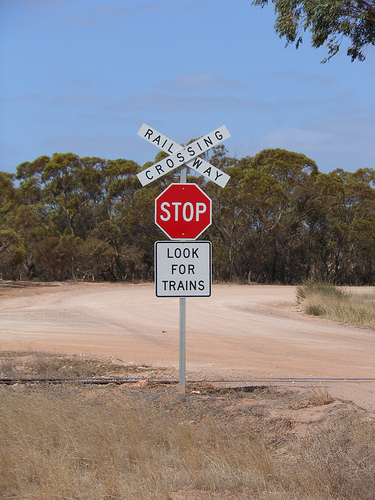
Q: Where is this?
A: This is at the road.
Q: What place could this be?
A: It is a road.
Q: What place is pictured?
A: It is a road.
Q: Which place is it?
A: It is a road.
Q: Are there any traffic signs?
A: Yes, there is a traffic sign.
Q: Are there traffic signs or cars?
A: Yes, there is a traffic sign.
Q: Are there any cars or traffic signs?
A: Yes, there is a traffic sign.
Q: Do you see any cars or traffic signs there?
A: Yes, there is a traffic sign.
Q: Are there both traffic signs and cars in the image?
A: No, there is a traffic sign but no cars.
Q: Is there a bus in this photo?
A: No, there are no buses.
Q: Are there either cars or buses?
A: No, there are no buses or cars.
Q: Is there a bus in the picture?
A: No, there are no buses.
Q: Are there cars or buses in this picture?
A: No, there are no buses or cars.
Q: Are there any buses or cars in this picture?
A: No, there are no buses or cars.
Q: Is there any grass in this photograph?
A: Yes, there is grass.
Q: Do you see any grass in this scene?
A: Yes, there is grass.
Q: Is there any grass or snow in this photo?
A: Yes, there is grass.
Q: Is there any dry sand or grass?
A: Yes, there is dry grass.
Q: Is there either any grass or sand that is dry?
A: Yes, the grass is dry.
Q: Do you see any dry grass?
A: Yes, there is dry grass.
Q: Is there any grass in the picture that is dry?
A: Yes, there is grass that is dry.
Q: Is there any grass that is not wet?
A: Yes, there is dry grass.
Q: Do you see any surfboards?
A: No, there are no surfboards.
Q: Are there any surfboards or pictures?
A: No, there are no surfboards or pictures.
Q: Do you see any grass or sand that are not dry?
A: No, there is grass but it is dry.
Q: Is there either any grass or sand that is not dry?
A: No, there is grass but it is dry.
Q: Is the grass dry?
A: Yes, the grass is dry.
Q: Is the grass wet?
A: No, the grass is dry.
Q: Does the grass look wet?
A: No, the grass is dry.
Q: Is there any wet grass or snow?
A: No, there is grass but it is dry.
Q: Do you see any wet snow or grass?
A: No, there is grass but it is dry.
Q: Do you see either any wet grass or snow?
A: No, there is grass but it is dry.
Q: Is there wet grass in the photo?
A: No, there is grass but it is dry.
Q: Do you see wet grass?
A: No, there is grass but it is dry.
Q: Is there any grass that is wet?
A: No, there is grass but it is dry.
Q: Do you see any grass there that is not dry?
A: No, there is grass but it is dry.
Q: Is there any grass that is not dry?
A: No, there is grass but it is dry.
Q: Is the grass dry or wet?
A: The grass is dry.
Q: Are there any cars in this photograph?
A: No, there are no cars.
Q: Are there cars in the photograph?
A: No, there are no cars.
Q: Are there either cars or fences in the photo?
A: No, there are no cars or fences.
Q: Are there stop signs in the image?
A: Yes, there is a stop sign.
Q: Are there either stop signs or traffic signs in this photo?
A: Yes, there is a stop sign.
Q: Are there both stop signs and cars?
A: No, there is a stop sign but no cars.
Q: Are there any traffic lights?
A: No, there are no traffic lights.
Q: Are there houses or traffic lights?
A: No, there are no traffic lights or houses.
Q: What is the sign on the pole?
A: The sign is a stop sign.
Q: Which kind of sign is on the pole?
A: The sign is a stop sign.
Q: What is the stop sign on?
A: The stop sign is on the pole.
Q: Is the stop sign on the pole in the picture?
A: Yes, the stop sign is on the pole.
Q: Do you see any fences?
A: No, there are no fences.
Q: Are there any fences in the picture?
A: No, there are no fences.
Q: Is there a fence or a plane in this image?
A: No, there are no fences or airplanes.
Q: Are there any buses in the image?
A: No, there are no buses.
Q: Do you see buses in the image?
A: No, there are no buses.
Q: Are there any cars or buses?
A: No, there are no buses or cars.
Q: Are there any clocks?
A: No, there are no clocks.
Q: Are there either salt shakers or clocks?
A: No, there are no clocks or salt shakers.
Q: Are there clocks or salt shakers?
A: No, there are no clocks or salt shakers.